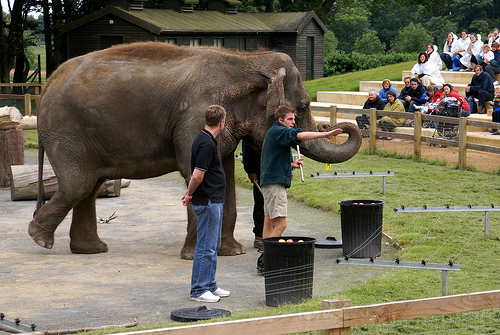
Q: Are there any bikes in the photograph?
A: No, there are no bikes.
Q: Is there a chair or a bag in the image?
A: No, there are no bags or chairs.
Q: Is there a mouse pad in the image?
A: No, there are no mouse pads.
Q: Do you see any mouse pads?
A: No, there are no mouse pads.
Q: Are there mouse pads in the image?
A: No, there are no mouse pads.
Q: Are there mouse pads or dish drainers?
A: No, there are no mouse pads or dish drainers.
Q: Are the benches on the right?
A: Yes, the benches are on the right of the image.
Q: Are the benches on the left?
A: No, the benches are on the right of the image.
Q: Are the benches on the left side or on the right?
A: The benches are on the right of the image.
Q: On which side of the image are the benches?
A: The benches are on the right of the image.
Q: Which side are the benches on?
A: The benches are on the right of the image.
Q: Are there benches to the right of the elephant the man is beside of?
A: Yes, there are benches to the right of the elephant.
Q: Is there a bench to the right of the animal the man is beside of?
A: Yes, there are benches to the right of the elephant.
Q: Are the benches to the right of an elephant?
A: Yes, the benches are to the right of an elephant.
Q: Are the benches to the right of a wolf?
A: No, the benches are to the right of an elephant.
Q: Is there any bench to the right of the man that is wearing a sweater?
A: Yes, there are benches to the right of the man.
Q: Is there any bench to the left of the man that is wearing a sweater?
A: No, the benches are to the right of the man.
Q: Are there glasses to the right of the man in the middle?
A: No, there are benches to the right of the man.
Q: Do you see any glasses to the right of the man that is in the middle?
A: No, there are benches to the right of the man.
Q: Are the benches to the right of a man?
A: Yes, the benches are to the right of a man.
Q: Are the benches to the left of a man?
A: No, the benches are to the right of a man.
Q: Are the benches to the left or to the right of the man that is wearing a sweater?
A: The benches are to the right of the man.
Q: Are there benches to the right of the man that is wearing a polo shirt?
A: Yes, there are benches to the right of the man.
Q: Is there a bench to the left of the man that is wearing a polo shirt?
A: No, the benches are to the right of the man.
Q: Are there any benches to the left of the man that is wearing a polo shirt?
A: No, the benches are to the right of the man.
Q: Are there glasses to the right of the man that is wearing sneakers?
A: No, there are benches to the right of the man.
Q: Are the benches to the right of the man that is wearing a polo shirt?
A: Yes, the benches are to the right of the man.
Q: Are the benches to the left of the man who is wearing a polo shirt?
A: No, the benches are to the right of the man.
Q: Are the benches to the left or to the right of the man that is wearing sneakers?
A: The benches are to the right of the man.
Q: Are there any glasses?
A: No, there are no glasses.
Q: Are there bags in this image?
A: No, there are no bags.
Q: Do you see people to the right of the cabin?
A: Yes, there are people to the right of the cabin.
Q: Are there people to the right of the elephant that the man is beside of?
A: Yes, there are people to the right of the elephant.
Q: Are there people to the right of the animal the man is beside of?
A: Yes, there are people to the right of the elephant.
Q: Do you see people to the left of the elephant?
A: No, the people are to the right of the elephant.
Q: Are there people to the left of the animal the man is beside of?
A: No, the people are to the right of the elephant.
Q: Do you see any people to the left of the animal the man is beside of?
A: No, the people are to the right of the elephant.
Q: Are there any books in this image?
A: No, there are no books.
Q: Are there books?
A: No, there are no books.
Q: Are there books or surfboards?
A: No, there are no books or surfboards.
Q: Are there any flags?
A: No, there are no flags.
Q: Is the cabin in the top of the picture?
A: Yes, the cabin is in the top of the image.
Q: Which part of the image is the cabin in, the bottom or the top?
A: The cabin is in the top of the image.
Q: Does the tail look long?
A: Yes, the tail is long.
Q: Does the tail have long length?
A: Yes, the tail is long.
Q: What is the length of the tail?
A: The tail is long.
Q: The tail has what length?
A: The tail is long.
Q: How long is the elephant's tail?
A: The tail is long.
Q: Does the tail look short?
A: No, the tail is long.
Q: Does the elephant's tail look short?
A: No, the tail is long.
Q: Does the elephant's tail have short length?
A: No, the tail is long.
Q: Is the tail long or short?
A: The tail is long.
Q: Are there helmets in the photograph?
A: No, there are no helmets.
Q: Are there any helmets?
A: No, there are no helmets.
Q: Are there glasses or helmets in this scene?
A: No, there are no helmets or glasses.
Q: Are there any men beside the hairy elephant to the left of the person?
A: Yes, there is a man beside the elephant.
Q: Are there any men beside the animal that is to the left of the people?
A: Yes, there is a man beside the elephant.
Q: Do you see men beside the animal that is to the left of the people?
A: Yes, there is a man beside the elephant.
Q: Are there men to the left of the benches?
A: Yes, there is a man to the left of the benches.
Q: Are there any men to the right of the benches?
A: No, the man is to the left of the benches.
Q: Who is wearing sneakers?
A: The man is wearing sneakers.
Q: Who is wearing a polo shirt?
A: The man is wearing a polo shirt.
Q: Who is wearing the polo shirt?
A: The man is wearing a polo shirt.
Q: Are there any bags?
A: No, there are no bags.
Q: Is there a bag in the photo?
A: No, there are no bags.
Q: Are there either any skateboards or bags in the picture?
A: No, there are no bags or skateboards.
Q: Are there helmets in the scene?
A: No, there are no helmets.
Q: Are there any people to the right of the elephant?
A: Yes, there is a person to the right of the elephant.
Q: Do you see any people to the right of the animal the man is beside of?
A: Yes, there is a person to the right of the elephant.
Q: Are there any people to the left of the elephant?
A: No, the person is to the right of the elephant.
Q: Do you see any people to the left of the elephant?
A: No, the person is to the right of the elephant.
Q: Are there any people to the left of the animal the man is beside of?
A: No, the person is to the right of the elephant.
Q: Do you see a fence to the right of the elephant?
A: No, there is a person to the right of the elephant.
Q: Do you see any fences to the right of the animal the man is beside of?
A: No, there is a person to the right of the elephant.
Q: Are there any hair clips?
A: No, there are no hair clips.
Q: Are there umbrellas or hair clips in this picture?
A: No, there are no hair clips or umbrellas.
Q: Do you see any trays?
A: No, there are no trays.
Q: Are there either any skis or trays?
A: No, there are no trays or skis.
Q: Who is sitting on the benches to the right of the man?
A: The crowd is sitting on the benches.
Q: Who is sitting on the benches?
A: The crowd is sitting on the benches.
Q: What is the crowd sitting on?
A: The crowd is sitting on the benches.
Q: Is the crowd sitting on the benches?
A: Yes, the crowd is sitting on the benches.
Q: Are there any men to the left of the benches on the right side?
A: Yes, there is a man to the left of the benches.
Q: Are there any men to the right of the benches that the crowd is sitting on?
A: No, the man is to the left of the benches.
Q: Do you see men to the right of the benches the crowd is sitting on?
A: No, the man is to the left of the benches.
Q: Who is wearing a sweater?
A: The man is wearing a sweater.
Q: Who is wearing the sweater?
A: The man is wearing a sweater.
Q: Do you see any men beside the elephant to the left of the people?
A: Yes, there is a man beside the elephant.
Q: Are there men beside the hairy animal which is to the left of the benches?
A: Yes, there is a man beside the elephant.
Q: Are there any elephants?
A: Yes, there is an elephant.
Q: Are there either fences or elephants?
A: Yes, there is an elephant.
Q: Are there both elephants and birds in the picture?
A: No, there is an elephant but no birds.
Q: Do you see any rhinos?
A: No, there are no rhinos.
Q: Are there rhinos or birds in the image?
A: No, there are no rhinos or birds.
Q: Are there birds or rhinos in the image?
A: No, there are no rhinos or birds.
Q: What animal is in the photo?
A: The animal is an elephant.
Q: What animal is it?
A: The animal is an elephant.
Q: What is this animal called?
A: This is an elephant.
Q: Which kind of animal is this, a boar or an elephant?
A: This is an elephant.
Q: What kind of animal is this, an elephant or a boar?
A: This is an elephant.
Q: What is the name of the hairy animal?
A: The animal is an elephant.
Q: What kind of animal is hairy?
A: The animal is an elephant.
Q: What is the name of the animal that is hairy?
A: The animal is an elephant.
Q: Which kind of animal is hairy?
A: The animal is an elephant.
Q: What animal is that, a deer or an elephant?
A: That is an elephant.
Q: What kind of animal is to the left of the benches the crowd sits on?
A: The animal is an elephant.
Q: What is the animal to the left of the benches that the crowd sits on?
A: The animal is an elephant.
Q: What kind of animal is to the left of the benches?
A: The animal is an elephant.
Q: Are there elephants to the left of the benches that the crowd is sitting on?
A: Yes, there is an elephant to the left of the benches.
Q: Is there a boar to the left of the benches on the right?
A: No, there is an elephant to the left of the benches.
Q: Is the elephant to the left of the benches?
A: Yes, the elephant is to the left of the benches.